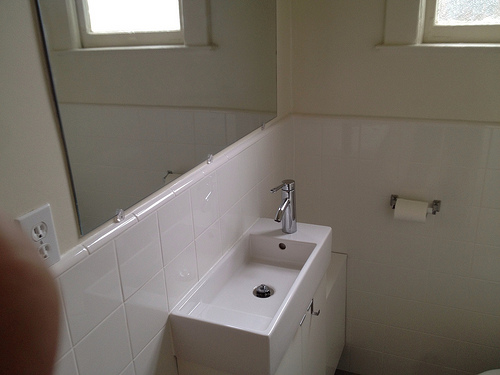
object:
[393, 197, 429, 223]
toilet paper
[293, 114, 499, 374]
wall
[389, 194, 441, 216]
mounted dispenser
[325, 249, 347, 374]
receptacle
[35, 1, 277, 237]
mirror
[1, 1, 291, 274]
tan wall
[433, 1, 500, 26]
window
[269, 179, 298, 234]
faucet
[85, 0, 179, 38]
window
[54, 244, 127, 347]
wall tiles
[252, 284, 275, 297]
drain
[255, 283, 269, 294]
stopper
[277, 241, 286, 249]
hole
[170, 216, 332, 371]
sink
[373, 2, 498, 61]
frame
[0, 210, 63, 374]
fingertip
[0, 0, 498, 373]
photo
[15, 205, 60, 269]
electrical outlet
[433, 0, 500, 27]
crackled glass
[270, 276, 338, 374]
cabinet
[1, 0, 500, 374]
bathroom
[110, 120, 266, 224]
plastic pegs